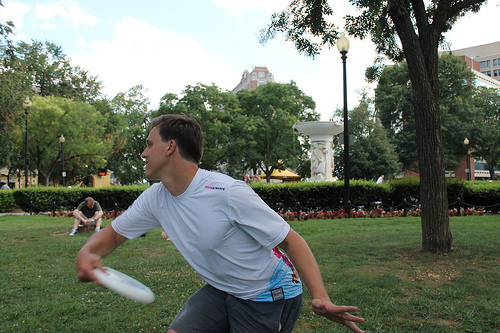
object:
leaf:
[1, 0, 498, 185]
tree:
[380, 3, 465, 255]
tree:
[233, 79, 320, 184]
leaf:
[290, 80, 296, 85]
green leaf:
[121, 112, 132, 125]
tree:
[1, 17, 139, 187]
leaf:
[202, 90, 207, 102]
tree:
[140, 77, 317, 186]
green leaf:
[159, 80, 319, 126]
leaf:
[28, 60, 106, 132]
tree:
[6, 30, 98, 191]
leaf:
[117, 95, 122, 102]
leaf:
[191, 90, 196, 95]